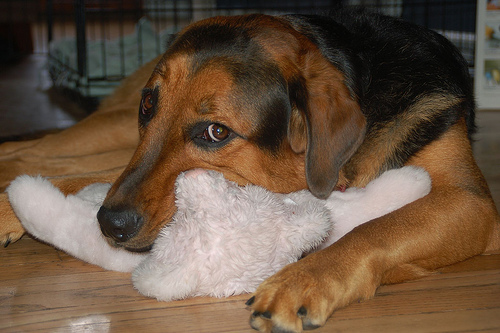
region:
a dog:
[125, 17, 428, 276]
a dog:
[132, 60, 332, 329]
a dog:
[162, 50, 187, 92]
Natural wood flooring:
[33, 266, 74, 318]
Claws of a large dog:
[232, 293, 313, 324]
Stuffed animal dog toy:
[9, 152, 446, 302]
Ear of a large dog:
[295, 63, 359, 199]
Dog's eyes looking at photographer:
[127, 67, 257, 167]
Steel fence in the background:
[82, 14, 127, 85]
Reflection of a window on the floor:
[60, 304, 115, 331]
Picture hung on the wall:
[482, 48, 499, 97]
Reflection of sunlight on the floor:
[26, 68, 63, 124]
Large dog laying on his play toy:
[17, 6, 485, 298]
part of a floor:
[74, 279, 108, 312]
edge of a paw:
[258, 287, 298, 324]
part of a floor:
[403, 283, 433, 313]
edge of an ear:
[308, 182, 334, 207]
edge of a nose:
[114, 215, 134, 233]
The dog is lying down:
[31, 22, 471, 319]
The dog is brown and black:
[37, 12, 448, 289]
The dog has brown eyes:
[136, 74, 240, 176]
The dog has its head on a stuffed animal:
[48, 21, 453, 303]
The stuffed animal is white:
[21, 119, 442, 278]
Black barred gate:
[56, 1, 194, 104]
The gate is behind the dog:
[61, 8, 463, 115]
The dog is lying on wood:
[26, 13, 481, 325]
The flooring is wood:
[22, 153, 469, 320]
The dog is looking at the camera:
[63, 3, 368, 243]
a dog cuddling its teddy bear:
[10, 159, 426, 293]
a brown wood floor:
[0, 115, 496, 323]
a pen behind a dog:
[38, 3, 479, 104]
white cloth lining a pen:
[50, 20, 171, 92]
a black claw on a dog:
[262, 305, 274, 319]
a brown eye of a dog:
[204, 124, 234, 140]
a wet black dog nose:
[97, 201, 143, 242]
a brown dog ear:
[294, 63, 355, 200]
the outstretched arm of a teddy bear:
[12, 168, 142, 266]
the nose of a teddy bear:
[182, 166, 209, 184]